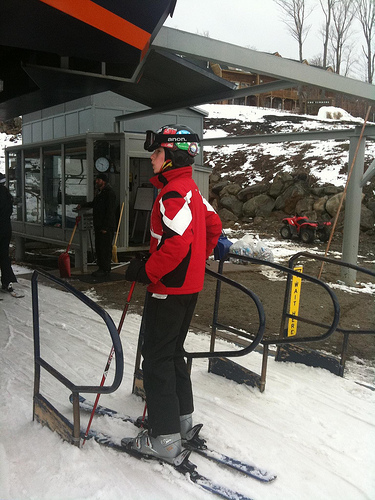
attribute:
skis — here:
[62, 394, 277, 499]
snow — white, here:
[0, 277, 374, 491]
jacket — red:
[141, 162, 223, 296]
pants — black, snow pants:
[136, 291, 200, 433]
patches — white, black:
[145, 190, 194, 284]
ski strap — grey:
[134, 438, 152, 448]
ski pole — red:
[77, 257, 145, 456]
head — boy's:
[144, 120, 202, 180]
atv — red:
[280, 212, 330, 241]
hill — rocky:
[203, 132, 373, 258]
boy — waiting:
[110, 117, 224, 463]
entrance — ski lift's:
[31, 253, 271, 436]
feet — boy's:
[128, 416, 194, 456]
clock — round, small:
[95, 153, 111, 177]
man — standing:
[73, 166, 124, 288]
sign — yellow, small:
[284, 253, 309, 337]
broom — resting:
[110, 197, 127, 265]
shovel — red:
[56, 215, 81, 277]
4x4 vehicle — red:
[274, 214, 327, 247]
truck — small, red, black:
[272, 212, 330, 241]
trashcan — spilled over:
[213, 233, 234, 264]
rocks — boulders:
[210, 151, 374, 260]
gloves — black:
[123, 256, 149, 287]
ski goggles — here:
[143, 130, 201, 153]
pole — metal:
[340, 141, 374, 283]